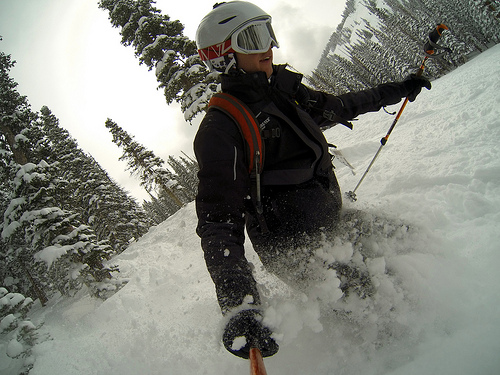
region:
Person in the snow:
[123, 0, 499, 367]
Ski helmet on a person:
[190, 5, 290, 82]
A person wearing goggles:
[194, 6, 304, 85]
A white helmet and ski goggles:
[182, 6, 296, 88]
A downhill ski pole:
[320, 22, 452, 227]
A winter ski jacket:
[187, 55, 439, 322]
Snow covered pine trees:
[2, 51, 192, 326]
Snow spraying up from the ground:
[95, 212, 484, 374]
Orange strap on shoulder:
[196, 80, 278, 194]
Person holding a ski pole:
[305, 0, 497, 145]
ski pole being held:
[332, 13, 453, 209]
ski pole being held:
[245, 323, 280, 374]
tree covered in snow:
[96, 114, 196, 209]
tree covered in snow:
[92, 1, 229, 131]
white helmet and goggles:
[188, 0, 285, 75]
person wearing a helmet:
[164, 3, 415, 373]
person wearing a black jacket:
[150, 0, 430, 374]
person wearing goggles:
[139, 1, 438, 373]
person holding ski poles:
[147, 3, 459, 373]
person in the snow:
[127, 1, 452, 373]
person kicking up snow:
[168, 3, 460, 374]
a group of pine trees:
[0, 38, 142, 324]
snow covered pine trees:
[0, 49, 143, 311]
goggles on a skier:
[222, 15, 297, 62]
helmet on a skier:
[183, 3, 283, 79]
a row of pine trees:
[307, 1, 497, 108]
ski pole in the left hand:
[312, 0, 467, 210]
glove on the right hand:
[213, 291, 288, 369]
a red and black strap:
[205, 88, 267, 172]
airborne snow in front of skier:
[272, 209, 396, 310]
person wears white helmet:
[184, 17, 271, 57]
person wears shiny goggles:
[235, 29, 297, 59]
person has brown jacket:
[221, 84, 336, 222]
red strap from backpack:
[205, 89, 301, 183]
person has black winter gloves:
[209, 284, 276, 372]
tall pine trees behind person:
[5, 101, 167, 253]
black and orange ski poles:
[337, 39, 441, 218]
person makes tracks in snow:
[287, 206, 406, 365]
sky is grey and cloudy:
[18, 1, 167, 119]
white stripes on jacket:
[212, 108, 266, 193]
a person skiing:
[153, 0, 464, 374]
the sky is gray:
[3, 0, 119, 105]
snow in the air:
[266, 275, 341, 341]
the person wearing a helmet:
[152, 1, 302, 74]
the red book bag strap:
[200, 75, 282, 222]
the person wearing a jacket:
[195, 77, 405, 313]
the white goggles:
[182, 17, 296, 61]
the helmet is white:
[180, 4, 306, 72]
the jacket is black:
[176, 65, 398, 317]